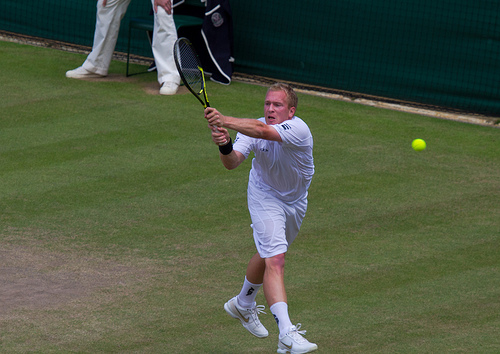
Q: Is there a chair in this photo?
A: Yes, there is a chair.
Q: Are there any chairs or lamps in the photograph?
A: Yes, there is a chair.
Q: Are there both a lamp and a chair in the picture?
A: No, there is a chair but no lamps.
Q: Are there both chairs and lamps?
A: No, there is a chair but no lamps.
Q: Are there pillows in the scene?
A: No, there are no pillows.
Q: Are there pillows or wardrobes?
A: No, there are no pillows or wardrobes.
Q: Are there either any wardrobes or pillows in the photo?
A: No, there are no pillows or wardrobes.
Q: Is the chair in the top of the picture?
A: Yes, the chair is in the top of the image.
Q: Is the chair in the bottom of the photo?
A: No, the chair is in the top of the image.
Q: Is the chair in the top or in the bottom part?
A: The chair is in the top of the image.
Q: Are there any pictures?
A: No, there are no pictures.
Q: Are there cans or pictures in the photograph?
A: No, there are no pictures or cans.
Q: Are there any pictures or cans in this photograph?
A: No, there are no pictures or cans.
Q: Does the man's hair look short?
A: Yes, the hair is short.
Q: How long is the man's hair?
A: The hair is short.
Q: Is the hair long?
A: No, the hair is short.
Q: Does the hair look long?
A: No, the hair is short.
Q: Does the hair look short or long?
A: The hair is short.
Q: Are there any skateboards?
A: No, there are no skateboards.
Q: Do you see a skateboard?
A: No, there are no skateboards.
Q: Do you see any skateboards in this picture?
A: No, there are no skateboards.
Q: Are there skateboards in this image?
A: No, there are no skateboards.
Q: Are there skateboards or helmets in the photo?
A: No, there are no skateboards or helmets.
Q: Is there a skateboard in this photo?
A: No, there are no skateboards.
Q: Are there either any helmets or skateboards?
A: No, there are no skateboards or helmets.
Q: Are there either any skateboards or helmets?
A: No, there are no skateboards or helmets.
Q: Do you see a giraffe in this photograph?
A: No, there are no giraffes.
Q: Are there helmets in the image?
A: No, there are no helmets.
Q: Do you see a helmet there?
A: No, there are no helmets.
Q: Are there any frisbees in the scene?
A: No, there are no frisbees.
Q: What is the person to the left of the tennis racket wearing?
A: The person is wearing pants.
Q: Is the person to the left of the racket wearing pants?
A: Yes, the person is wearing pants.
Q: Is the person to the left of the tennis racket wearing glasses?
A: No, the person is wearing pants.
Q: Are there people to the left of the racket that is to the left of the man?
A: Yes, there is a person to the left of the racket.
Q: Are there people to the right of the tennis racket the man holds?
A: No, the person is to the left of the racket.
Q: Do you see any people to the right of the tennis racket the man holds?
A: No, the person is to the left of the racket.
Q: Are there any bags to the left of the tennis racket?
A: No, there is a person to the left of the tennis racket.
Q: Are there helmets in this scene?
A: No, there are no helmets.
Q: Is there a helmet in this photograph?
A: No, there are no helmets.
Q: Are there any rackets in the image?
A: Yes, there is a racket.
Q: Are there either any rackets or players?
A: Yes, there is a racket.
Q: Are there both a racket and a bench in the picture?
A: No, there is a racket but no benches.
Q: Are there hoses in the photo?
A: No, there are no hoses.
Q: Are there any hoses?
A: No, there are no hoses.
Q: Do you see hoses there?
A: No, there are no hoses.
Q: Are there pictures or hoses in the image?
A: No, there are no hoses or pictures.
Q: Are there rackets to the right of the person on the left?
A: Yes, there is a racket to the right of the person.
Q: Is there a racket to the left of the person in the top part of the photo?
A: No, the racket is to the right of the person.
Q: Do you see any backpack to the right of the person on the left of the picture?
A: No, there is a racket to the right of the person.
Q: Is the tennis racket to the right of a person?
A: Yes, the tennis racket is to the right of a person.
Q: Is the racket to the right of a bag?
A: No, the racket is to the right of a person.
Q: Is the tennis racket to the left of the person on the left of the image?
A: No, the tennis racket is to the right of the person.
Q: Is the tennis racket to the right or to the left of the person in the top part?
A: The tennis racket is to the right of the person.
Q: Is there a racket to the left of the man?
A: Yes, there is a racket to the left of the man.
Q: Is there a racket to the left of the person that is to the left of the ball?
A: Yes, there is a racket to the left of the man.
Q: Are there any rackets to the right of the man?
A: No, the racket is to the left of the man.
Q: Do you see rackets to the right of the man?
A: No, the racket is to the left of the man.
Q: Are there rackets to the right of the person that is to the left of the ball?
A: No, the racket is to the left of the man.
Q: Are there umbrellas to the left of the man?
A: No, there is a racket to the left of the man.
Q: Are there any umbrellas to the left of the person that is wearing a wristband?
A: No, there is a racket to the left of the man.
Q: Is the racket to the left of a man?
A: Yes, the racket is to the left of a man.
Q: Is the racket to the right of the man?
A: No, the racket is to the left of the man.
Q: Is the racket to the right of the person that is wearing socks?
A: No, the racket is to the left of the man.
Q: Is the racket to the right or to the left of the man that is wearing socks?
A: The racket is to the left of the man.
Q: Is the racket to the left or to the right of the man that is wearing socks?
A: The racket is to the left of the man.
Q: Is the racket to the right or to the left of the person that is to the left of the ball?
A: The racket is to the left of the man.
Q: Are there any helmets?
A: No, there are no helmets.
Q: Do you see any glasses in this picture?
A: No, there are no glasses.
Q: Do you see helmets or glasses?
A: No, there are no glasses or helmets.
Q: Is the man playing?
A: Yes, the man is playing.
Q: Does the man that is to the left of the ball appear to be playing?
A: Yes, the man is playing.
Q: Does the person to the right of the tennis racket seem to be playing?
A: Yes, the man is playing.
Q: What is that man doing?
A: The man is playing.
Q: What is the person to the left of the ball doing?
A: The man is playing.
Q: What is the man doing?
A: The man is playing.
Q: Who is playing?
A: The man is playing.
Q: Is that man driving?
A: No, the man is playing.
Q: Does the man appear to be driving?
A: No, the man is playing.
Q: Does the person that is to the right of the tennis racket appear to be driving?
A: No, the man is playing.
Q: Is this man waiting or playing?
A: The man is playing.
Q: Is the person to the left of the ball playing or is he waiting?
A: The man is playing.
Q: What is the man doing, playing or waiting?
A: The man is playing.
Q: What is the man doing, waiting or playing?
A: The man is playing.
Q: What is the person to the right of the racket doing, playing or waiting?
A: The man is playing.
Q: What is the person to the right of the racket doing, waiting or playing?
A: The man is playing.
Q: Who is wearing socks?
A: The man is wearing socks.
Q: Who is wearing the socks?
A: The man is wearing socks.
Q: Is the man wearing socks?
A: Yes, the man is wearing socks.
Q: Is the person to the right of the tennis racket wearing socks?
A: Yes, the man is wearing socks.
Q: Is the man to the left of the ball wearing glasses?
A: No, the man is wearing socks.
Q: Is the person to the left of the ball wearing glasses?
A: No, the man is wearing socks.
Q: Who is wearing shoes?
A: The man is wearing shoes.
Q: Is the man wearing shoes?
A: Yes, the man is wearing shoes.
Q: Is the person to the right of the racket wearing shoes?
A: Yes, the man is wearing shoes.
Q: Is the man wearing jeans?
A: No, the man is wearing shoes.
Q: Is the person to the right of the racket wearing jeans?
A: No, the man is wearing shoes.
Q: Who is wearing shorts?
A: The man is wearing shorts.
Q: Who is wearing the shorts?
A: The man is wearing shorts.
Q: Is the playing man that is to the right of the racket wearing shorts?
A: Yes, the man is wearing shorts.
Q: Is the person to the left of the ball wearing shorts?
A: Yes, the man is wearing shorts.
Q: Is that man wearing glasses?
A: No, the man is wearing shorts.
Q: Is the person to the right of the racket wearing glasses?
A: No, the man is wearing shorts.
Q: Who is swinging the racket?
A: The man is swinging the racket.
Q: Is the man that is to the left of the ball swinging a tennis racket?
A: Yes, the man is swinging a tennis racket.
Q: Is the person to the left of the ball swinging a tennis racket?
A: Yes, the man is swinging a tennis racket.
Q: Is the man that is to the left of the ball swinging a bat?
A: No, the man is swinging a tennis racket.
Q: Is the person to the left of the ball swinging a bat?
A: No, the man is swinging a tennis racket.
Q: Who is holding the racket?
A: The man is holding the racket.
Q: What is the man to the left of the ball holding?
A: The man is holding the racket.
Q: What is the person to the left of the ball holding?
A: The man is holding the racket.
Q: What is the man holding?
A: The man is holding the racket.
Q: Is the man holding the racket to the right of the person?
A: Yes, the man is holding the tennis racket.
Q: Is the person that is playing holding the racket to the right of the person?
A: Yes, the man is holding the tennis racket.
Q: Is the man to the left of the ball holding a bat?
A: No, the man is holding the tennis racket.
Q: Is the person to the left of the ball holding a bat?
A: No, the man is holding the tennis racket.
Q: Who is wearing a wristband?
A: The man is wearing a wristband.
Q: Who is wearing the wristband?
A: The man is wearing a wristband.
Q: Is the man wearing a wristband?
A: Yes, the man is wearing a wristband.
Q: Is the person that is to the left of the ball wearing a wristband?
A: Yes, the man is wearing a wristband.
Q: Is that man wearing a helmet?
A: No, the man is wearing a wristband.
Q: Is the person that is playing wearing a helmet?
A: No, the man is wearing a wristband.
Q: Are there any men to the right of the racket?
A: Yes, there is a man to the right of the racket.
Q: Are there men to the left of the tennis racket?
A: No, the man is to the right of the tennis racket.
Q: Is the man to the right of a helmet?
A: No, the man is to the right of the tennis racket.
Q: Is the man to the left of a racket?
A: No, the man is to the right of a racket.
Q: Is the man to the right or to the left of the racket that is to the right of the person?
A: The man is to the right of the racket.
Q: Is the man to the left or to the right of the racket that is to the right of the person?
A: The man is to the right of the racket.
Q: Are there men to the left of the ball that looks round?
A: Yes, there is a man to the left of the ball.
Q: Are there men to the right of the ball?
A: No, the man is to the left of the ball.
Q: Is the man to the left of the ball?
A: Yes, the man is to the left of the ball.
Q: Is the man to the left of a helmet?
A: No, the man is to the left of the ball.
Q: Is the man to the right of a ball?
A: No, the man is to the left of a ball.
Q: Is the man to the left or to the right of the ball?
A: The man is to the left of the ball.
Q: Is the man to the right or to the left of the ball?
A: The man is to the left of the ball.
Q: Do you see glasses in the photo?
A: No, there are no glasses.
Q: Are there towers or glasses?
A: No, there are no glasses or towers.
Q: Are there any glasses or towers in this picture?
A: No, there are no glasses or towers.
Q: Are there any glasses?
A: No, there are no glasses.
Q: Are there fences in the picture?
A: Yes, there is a fence.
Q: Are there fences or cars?
A: Yes, there is a fence.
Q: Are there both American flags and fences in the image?
A: No, there is a fence but no American flags.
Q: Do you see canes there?
A: No, there are no canes.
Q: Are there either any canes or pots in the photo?
A: No, there are no canes or pots.